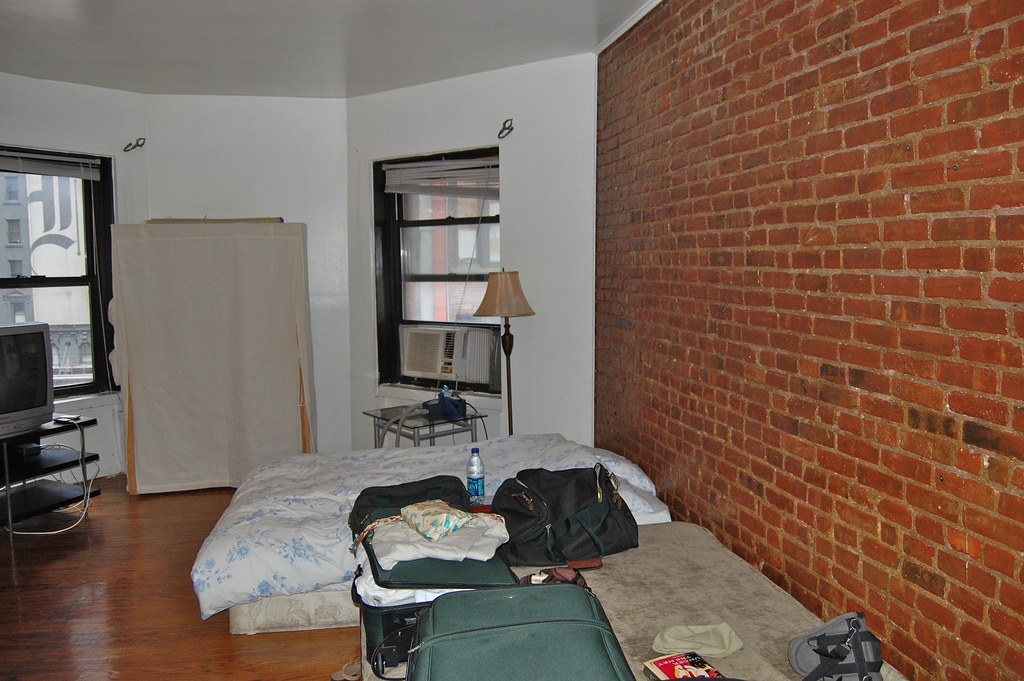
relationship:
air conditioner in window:
[380, 308, 504, 391] [376, 154, 509, 390]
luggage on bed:
[415, 587, 668, 671] [345, 495, 902, 676]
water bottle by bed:
[459, 447, 489, 505] [219, 425, 694, 626]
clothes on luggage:
[364, 483, 507, 557] [350, 470, 534, 645]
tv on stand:
[3, 317, 65, 439] [3, 400, 108, 556]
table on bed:
[354, 394, 487, 446] [211, 434, 668, 644]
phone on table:
[408, 381, 476, 417] [360, 390, 494, 444]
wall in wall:
[503, 69, 593, 436] [503, 50, 599, 445]